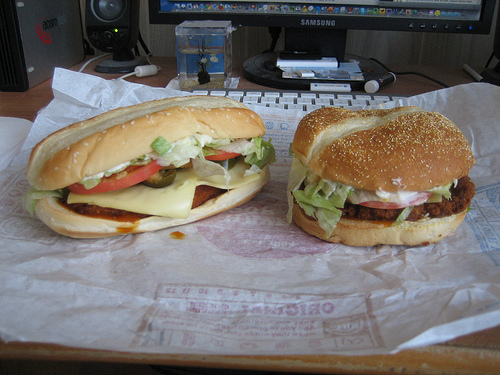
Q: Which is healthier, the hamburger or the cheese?
A: The cheese is healthier than the hamburger.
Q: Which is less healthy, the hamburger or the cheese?
A: The hamburger is less healthy than the cheese.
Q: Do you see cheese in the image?
A: Yes, there is cheese.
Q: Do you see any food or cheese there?
A: Yes, there is cheese.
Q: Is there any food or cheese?
A: Yes, there is cheese.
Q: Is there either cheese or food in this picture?
A: Yes, there is cheese.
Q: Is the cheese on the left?
A: Yes, the cheese is on the left of the image.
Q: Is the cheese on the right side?
A: No, the cheese is on the left of the image.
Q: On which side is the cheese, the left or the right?
A: The cheese is on the left of the image.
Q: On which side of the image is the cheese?
A: The cheese is on the left of the image.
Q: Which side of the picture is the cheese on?
A: The cheese is on the left of the image.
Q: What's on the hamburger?
A: The cheese is on the hamburger.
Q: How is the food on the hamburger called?
A: The food is cheese.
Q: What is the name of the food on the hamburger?
A: The food is cheese.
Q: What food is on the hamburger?
A: The food is cheese.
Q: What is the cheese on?
A: The cheese is on the hamburger.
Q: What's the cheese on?
A: The cheese is on the hamburger.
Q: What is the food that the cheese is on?
A: The food is a hamburger.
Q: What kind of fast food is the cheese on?
A: The cheese is on the hamburger.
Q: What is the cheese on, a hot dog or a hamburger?
A: The cheese is on a hamburger.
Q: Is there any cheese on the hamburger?
A: Yes, there is cheese on the hamburger.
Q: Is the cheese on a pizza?
A: No, the cheese is on the hamburger.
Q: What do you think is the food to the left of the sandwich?
A: The food is cheese.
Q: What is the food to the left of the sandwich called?
A: The food is cheese.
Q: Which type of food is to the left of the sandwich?
A: The food is cheese.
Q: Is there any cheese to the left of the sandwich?
A: Yes, there is cheese to the left of the sandwich.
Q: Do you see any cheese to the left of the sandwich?
A: Yes, there is cheese to the left of the sandwich.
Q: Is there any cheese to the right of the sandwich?
A: No, the cheese is to the left of the sandwich.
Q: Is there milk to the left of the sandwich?
A: No, there is cheese to the left of the sandwich.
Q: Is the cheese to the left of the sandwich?
A: Yes, the cheese is to the left of the sandwich.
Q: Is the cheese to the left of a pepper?
A: No, the cheese is to the left of the sandwich.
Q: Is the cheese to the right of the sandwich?
A: No, the cheese is to the left of the sandwich.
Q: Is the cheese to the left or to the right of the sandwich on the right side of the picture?
A: The cheese is to the left of the sandwich.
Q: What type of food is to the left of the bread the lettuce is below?
A: The food is cheese.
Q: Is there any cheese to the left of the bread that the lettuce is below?
A: Yes, there is cheese to the left of the bread.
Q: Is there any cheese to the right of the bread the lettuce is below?
A: No, the cheese is to the left of the bread.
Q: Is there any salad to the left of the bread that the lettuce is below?
A: No, there is cheese to the left of the bread.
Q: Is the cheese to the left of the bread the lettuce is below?
A: Yes, the cheese is to the left of the bread.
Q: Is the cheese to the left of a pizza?
A: No, the cheese is to the left of the bread.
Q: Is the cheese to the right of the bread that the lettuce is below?
A: No, the cheese is to the left of the bread.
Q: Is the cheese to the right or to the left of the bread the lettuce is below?
A: The cheese is to the left of the bread.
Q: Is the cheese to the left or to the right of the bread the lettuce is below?
A: The cheese is to the left of the bread.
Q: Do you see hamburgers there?
A: Yes, there is a hamburger.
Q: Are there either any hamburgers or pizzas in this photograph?
A: Yes, there is a hamburger.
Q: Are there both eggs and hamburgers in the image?
A: No, there is a hamburger but no eggs.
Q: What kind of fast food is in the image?
A: The fast food is a hamburger.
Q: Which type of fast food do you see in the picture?
A: The fast food is a hamburger.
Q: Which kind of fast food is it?
A: The food is a hamburger.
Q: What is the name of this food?
A: This is a hamburger.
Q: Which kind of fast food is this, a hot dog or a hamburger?
A: This is a hamburger.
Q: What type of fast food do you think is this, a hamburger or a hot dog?
A: This is a hamburger.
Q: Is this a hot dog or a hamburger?
A: This is a hamburger.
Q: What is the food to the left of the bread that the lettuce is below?
A: The food is a hamburger.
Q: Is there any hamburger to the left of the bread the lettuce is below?
A: Yes, there is a hamburger to the left of the bread.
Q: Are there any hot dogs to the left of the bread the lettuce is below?
A: No, there is a hamburger to the left of the bread.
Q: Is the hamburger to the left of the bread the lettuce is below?
A: Yes, the hamburger is to the left of the bread.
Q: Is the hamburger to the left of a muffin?
A: No, the hamburger is to the left of the bread.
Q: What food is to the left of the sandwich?
A: The food is a hamburger.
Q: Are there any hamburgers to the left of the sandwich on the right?
A: Yes, there is a hamburger to the left of the sandwich.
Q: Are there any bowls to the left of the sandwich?
A: No, there is a hamburger to the left of the sandwich.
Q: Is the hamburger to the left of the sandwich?
A: Yes, the hamburger is to the left of the sandwich.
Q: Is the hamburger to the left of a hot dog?
A: No, the hamburger is to the left of the sandwich.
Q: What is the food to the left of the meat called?
A: The food is a hamburger.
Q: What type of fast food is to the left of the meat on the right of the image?
A: The food is a hamburger.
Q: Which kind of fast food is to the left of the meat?
A: The food is a hamburger.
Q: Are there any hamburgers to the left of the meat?
A: Yes, there is a hamburger to the left of the meat.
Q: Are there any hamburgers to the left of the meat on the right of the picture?
A: Yes, there is a hamburger to the left of the meat.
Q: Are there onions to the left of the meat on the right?
A: No, there is a hamburger to the left of the meat.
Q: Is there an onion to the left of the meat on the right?
A: No, there is a hamburger to the left of the meat.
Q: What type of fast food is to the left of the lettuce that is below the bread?
A: The food is a hamburger.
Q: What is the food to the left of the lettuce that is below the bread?
A: The food is a hamburger.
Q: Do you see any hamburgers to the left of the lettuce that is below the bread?
A: Yes, there is a hamburger to the left of the lettuce.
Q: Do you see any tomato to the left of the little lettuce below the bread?
A: No, there is a hamburger to the left of the lettuce.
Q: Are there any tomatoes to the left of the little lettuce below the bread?
A: No, there is a hamburger to the left of the lettuce.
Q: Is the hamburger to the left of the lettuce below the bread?
A: Yes, the hamburger is to the left of the lettuce.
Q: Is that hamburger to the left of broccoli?
A: No, the hamburger is to the left of the lettuce.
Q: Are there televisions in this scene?
A: Yes, there is a television.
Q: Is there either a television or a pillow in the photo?
A: Yes, there is a television.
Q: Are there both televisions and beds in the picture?
A: No, there is a television but no beds.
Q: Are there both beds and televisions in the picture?
A: No, there is a television but no beds.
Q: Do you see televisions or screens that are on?
A: Yes, the television is on.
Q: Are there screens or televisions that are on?
A: Yes, the television is on.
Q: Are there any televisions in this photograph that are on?
A: Yes, there is a television that is on.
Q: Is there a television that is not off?
A: Yes, there is a television that is on.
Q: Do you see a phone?
A: No, there are no phones.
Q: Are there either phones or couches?
A: No, there are no phones or couches.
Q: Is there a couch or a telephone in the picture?
A: No, there are no phones or couches.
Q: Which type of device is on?
A: The device is a television.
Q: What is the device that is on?
A: The device is a television.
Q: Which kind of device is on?
A: The device is a television.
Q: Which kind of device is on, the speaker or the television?
A: The television is on.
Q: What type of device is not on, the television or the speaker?
A: The speaker is not on.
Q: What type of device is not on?
A: The device is a speaker.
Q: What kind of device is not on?
A: The device is a speaker.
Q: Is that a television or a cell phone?
A: That is a television.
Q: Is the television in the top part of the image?
A: Yes, the television is in the top of the image.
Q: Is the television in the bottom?
A: No, the television is in the top of the image.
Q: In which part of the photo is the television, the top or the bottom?
A: The television is in the top of the image.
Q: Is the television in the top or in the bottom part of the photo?
A: The television is in the top of the image.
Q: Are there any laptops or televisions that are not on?
A: No, there is a television but it is on.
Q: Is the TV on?
A: Yes, the TV is on.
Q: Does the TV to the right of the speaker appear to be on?
A: Yes, the TV is on.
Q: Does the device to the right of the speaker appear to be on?
A: Yes, the TV is on.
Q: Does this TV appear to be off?
A: No, the TV is on.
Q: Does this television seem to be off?
A: No, the television is on.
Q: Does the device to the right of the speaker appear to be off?
A: No, the television is on.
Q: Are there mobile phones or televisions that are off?
A: No, there is a television but it is on.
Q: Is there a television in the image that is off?
A: No, there is a television but it is on.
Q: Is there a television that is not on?
A: No, there is a television but it is on.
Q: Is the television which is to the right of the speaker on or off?
A: The TV is on.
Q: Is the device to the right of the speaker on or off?
A: The TV is on.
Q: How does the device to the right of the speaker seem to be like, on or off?
A: The TV is on.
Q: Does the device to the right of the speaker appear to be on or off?
A: The TV is on.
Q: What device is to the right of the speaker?
A: The device is a television.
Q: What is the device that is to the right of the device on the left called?
A: The device is a television.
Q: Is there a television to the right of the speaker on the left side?
A: Yes, there is a television to the right of the speaker.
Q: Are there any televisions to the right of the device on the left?
A: Yes, there is a television to the right of the speaker.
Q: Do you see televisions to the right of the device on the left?
A: Yes, there is a television to the right of the speaker.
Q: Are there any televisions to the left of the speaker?
A: No, the television is to the right of the speaker.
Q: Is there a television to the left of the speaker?
A: No, the television is to the right of the speaker.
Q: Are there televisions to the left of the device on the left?
A: No, the television is to the right of the speaker.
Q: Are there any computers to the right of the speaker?
A: No, there is a television to the right of the speaker.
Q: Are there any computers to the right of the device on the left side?
A: No, there is a television to the right of the speaker.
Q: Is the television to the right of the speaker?
A: Yes, the television is to the right of the speaker.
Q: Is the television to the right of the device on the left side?
A: Yes, the television is to the right of the speaker.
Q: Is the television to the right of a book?
A: No, the television is to the right of the speaker.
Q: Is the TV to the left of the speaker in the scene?
A: No, the TV is to the right of the speaker.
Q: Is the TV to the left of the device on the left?
A: No, the TV is to the right of the speaker.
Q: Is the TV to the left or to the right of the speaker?
A: The TV is to the right of the speaker.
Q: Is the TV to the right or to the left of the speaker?
A: The TV is to the right of the speaker.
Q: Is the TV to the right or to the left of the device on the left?
A: The TV is to the right of the speaker.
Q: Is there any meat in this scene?
A: Yes, there is meat.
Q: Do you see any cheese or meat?
A: Yes, there is meat.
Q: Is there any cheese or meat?
A: Yes, there is meat.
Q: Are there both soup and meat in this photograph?
A: No, there is meat but no soup.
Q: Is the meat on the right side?
A: Yes, the meat is on the right of the image.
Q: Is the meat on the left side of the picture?
A: No, the meat is on the right of the image.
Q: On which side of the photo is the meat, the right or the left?
A: The meat is on the right of the image.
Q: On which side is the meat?
A: The meat is on the right of the image.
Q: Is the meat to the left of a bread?
A: No, the meat is to the right of a bread.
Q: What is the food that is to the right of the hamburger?
A: The food is meat.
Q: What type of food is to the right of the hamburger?
A: The food is meat.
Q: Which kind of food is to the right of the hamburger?
A: The food is meat.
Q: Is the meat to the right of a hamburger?
A: Yes, the meat is to the right of a hamburger.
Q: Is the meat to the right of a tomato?
A: No, the meat is to the right of a hamburger.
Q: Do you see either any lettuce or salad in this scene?
A: Yes, there is lettuce.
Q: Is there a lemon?
A: No, there are no lemons.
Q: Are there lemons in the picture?
A: No, there are no lemons.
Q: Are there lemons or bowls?
A: No, there are no lemons or bowls.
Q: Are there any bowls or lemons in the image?
A: No, there are no lemons or bowls.